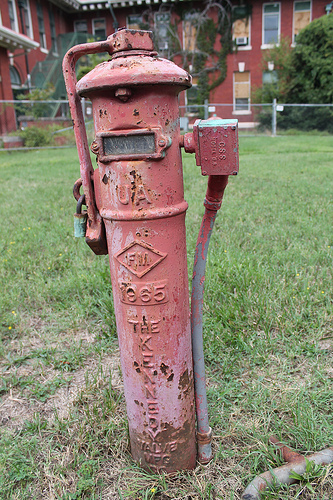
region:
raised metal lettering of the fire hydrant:
[110, 217, 191, 457]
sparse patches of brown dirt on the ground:
[0, 321, 97, 436]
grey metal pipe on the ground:
[239, 418, 331, 493]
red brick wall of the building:
[249, 13, 262, 82]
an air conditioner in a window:
[231, 33, 252, 49]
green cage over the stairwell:
[16, 31, 77, 112]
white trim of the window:
[261, 4, 283, 52]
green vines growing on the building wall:
[174, 5, 248, 99]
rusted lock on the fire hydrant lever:
[64, 170, 109, 254]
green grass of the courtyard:
[250, 155, 321, 300]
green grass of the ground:
[235, 241, 308, 331]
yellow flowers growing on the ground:
[0, 220, 59, 321]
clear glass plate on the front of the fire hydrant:
[101, 130, 157, 162]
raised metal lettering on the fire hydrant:
[115, 229, 182, 454]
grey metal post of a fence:
[269, 97, 279, 136]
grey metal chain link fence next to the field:
[242, 103, 327, 138]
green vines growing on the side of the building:
[189, 10, 235, 97]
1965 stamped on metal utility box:
[119, 279, 169, 307]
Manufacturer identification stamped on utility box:
[123, 319, 182, 465]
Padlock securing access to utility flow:
[73, 197, 92, 238]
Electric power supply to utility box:
[179, 119, 250, 464]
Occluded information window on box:
[94, 129, 162, 159]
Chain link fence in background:
[1, 98, 329, 138]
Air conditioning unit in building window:
[235, 35, 248, 46]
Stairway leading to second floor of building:
[13, 31, 98, 117]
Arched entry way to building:
[4, 63, 33, 132]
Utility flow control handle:
[58, 27, 155, 254]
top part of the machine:
[90, 28, 153, 53]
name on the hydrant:
[132, 327, 177, 461]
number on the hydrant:
[112, 282, 176, 307]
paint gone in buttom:
[109, 429, 193, 467]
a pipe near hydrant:
[186, 250, 233, 494]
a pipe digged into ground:
[190, 448, 220, 482]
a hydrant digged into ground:
[110, 415, 221, 497]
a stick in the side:
[226, 415, 308, 494]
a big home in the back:
[190, 1, 331, 127]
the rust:
[115, 368, 216, 495]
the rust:
[119, 385, 209, 487]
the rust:
[100, 397, 219, 496]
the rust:
[85, 384, 208, 493]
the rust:
[110, 380, 209, 484]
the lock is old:
[54, 184, 99, 252]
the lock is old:
[58, 182, 97, 241]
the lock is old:
[57, 183, 93, 239]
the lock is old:
[55, 186, 94, 251]